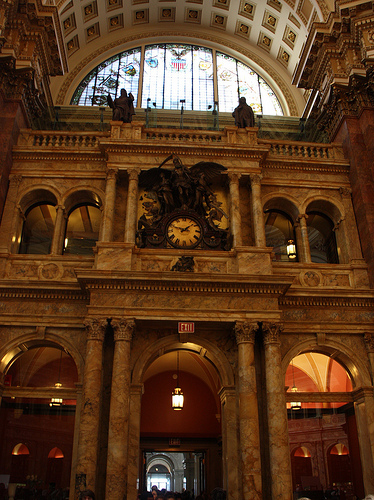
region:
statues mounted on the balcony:
[107, 88, 135, 123]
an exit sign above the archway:
[177, 320, 195, 333]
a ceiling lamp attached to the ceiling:
[172, 351, 184, 410]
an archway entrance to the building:
[130, 334, 238, 498]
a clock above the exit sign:
[163, 212, 202, 249]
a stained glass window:
[62, 35, 292, 116]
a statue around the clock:
[137, 154, 233, 249]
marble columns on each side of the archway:
[234, 321, 260, 498]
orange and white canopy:
[11, 441, 28, 455]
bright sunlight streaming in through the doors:
[146, 471, 171, 489]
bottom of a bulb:
[178, 396, 183, 402]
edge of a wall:
[87, 426, 98, 460]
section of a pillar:
[123, 411, 130, 424]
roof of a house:
[351, 360, 353, 362]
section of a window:
[153, 476, 164, 477]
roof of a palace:
[162, 364, 168, 374]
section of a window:
[159, 471, 170, 482]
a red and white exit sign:
[171, 315, 206, 341]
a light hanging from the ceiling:
[167, 375, 194, 413]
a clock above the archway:
[160, 205, 212, 248]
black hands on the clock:
[175, 222, 197, 234]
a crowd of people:
[153, 484, 176, 498]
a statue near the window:
[105, 72, 142, 121]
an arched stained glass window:
[130, 51, 201, 93]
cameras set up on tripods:
[150, 97, 219, 127]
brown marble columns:
[244, 346, 285, 497]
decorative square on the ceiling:
[102, 4, 273, 34]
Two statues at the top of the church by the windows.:
[105, 86, 255, 127]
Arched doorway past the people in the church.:
[146, 453, 173, 494]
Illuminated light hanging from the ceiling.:
[171, 383, 184, 412]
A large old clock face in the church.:
[165, 216, 201, 248]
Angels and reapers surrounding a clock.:
[138, 152, 232, 249]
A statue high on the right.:
[232, 95, 256, 130]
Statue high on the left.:
[106, 86, 136, 126]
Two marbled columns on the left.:
[73, 315, 135, 498]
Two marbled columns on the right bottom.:
[233, 318, 295, 498]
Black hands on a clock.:
[168, 221, 194, 233]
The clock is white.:
[164, 213, 201, 250]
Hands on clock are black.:
[166, 218, 200, 246]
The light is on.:
[167, 386, 184, 411]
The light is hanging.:
[166, 343, 192, 415]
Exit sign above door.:
[173, 316, 194, 335]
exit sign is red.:
[175, 317, 197, 335]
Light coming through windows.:
[133, 465, 189, 493]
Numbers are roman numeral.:
[164, 214, 202, 247]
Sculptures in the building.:
[101, 84, 259, 136]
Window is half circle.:
[62, 30, 294, 128]